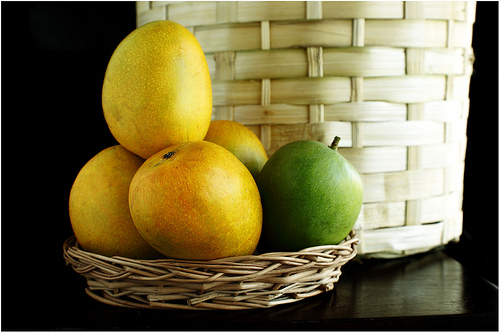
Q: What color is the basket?
A: Tan.